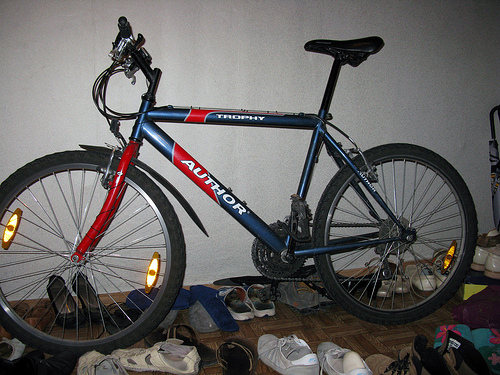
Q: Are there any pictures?
A: No, there are no pictures.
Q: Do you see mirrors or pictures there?
A: No, there are no pictures or mirrors.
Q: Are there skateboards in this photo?
A: No, there are no skateboards.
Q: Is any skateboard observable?
A: No, there are no skateboards.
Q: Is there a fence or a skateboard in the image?
A: No, there are no skateboards or fences.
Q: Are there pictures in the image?
A: No, there are no pictures.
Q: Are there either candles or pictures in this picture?
A: No, there are no pictures or candles.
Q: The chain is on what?
A: The chain is on the bicycle.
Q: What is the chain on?
A: The chain is on the bicycle.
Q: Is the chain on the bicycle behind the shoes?
A: Yes, the chain is on the bicycle.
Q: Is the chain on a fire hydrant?
A: No, the chain is on the bicycle.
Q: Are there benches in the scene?
A: No, there are no benches.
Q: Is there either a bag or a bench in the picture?
A: No, there are no benches or bags.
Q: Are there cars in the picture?
A: No, there are no cars.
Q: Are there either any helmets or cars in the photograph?
A: No, there are no cars or helmets.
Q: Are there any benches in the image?
A: No, there are no benches.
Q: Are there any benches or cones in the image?
A: No, there are no benches or cones.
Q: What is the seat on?
A: The seat is on the bicycle.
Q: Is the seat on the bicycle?
A: Yes, the seat is on the bicycle.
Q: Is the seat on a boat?
A: No, the seat is on the bicycle.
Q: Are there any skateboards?
A: No, there are no skateboards.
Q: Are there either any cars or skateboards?
A: No, there are no skateboards or cars.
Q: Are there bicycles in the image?
A: Yes, there is a bicycle.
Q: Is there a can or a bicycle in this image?
A: Yes, there is a bicycle.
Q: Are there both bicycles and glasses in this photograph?
A: No, there is a bicycle but no glasses.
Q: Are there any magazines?
A: No, there are no magazines.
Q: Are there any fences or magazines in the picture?
A: No, there are no magazines or fences.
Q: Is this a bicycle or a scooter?
A: This is a bicycle.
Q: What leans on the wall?
A: The bicycle leans on the wall.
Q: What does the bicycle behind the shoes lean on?
A: The bicycle leans on the wall.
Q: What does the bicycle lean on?
A: The bicycle leans on the wall.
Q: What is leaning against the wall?
A: The bicycle is leaning against the wall.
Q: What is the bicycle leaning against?
A: The bicycle is leaning against the wall.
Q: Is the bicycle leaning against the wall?
A: Yes, the bicycle is leaning against the wall.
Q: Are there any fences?
A: No, there are no fences.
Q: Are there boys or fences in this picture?
A: No, there are no fences or boys.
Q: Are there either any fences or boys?
A: No, there are no fences or boys.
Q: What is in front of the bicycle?
A: The shoes are in front of the bicycle.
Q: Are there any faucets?
A: No, there are no faucets.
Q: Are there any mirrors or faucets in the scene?
A: No, there are no faucets or mirrors.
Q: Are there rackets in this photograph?
A: No, there are no rackets.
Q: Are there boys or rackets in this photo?
A: No, there are no rackets or boys.